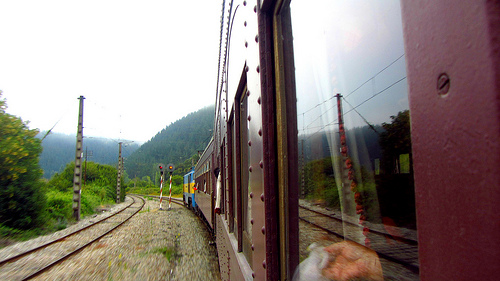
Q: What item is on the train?
A: Rivets.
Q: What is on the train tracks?
A: Gravel.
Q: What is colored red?
A: Train.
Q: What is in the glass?
A: A reflection.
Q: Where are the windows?
A: Train car.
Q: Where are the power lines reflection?
A: In the window.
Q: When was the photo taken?
A: Daytime.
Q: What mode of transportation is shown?
A: Train.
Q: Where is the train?
A: On the tracks.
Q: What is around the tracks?
A: Gravel.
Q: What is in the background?
A: Trees.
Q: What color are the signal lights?
A: Red.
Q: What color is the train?
A: Burgundy.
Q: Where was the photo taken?
A: Next to a train.